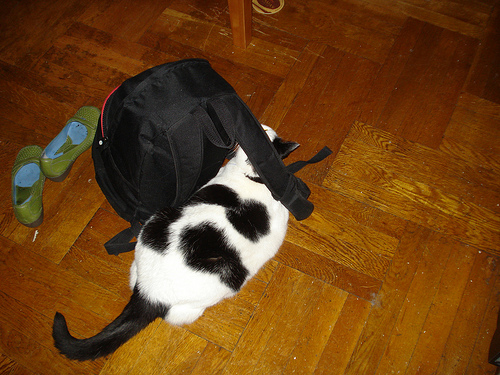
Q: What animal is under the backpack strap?
A: A cat.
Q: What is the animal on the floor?
A: Cat.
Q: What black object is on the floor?
A: Backpack.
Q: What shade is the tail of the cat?
A: Black.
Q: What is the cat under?
A: Backpack.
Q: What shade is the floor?
A: Wooden brown.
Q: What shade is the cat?
A: Black and white.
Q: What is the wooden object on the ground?
A: Leg chair.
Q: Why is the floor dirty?
A: White specks.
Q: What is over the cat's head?
A: Back pack strap.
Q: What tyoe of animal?
A: Cat.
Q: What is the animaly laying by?
A: A backpack.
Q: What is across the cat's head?
A: A strap.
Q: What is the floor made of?
A: Wood.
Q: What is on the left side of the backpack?
A: A pair of shoes.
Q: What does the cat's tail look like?
A: Solid black.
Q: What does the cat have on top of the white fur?
A: Black spots.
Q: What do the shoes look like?
A: Green flats.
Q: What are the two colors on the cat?
A: Black and white.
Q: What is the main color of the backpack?
A: Black.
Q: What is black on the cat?
A: Tail, ears and patches.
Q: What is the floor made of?
A: Wood.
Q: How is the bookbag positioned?
A: Upright and closed.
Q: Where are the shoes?
A: On floor.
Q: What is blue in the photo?
A: Shoe insoles.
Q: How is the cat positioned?
A: Laying down.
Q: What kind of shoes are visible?
A: Girls flats.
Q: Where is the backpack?
A: On the floor.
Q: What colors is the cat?
A: Black and white.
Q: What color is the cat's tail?
A: Black.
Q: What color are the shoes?
A: Green.